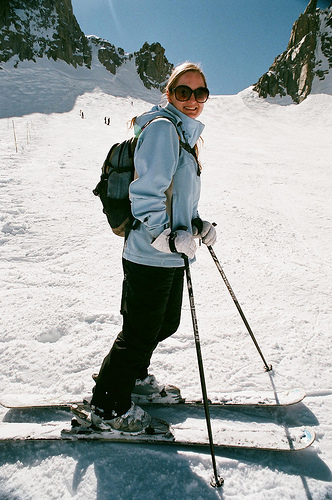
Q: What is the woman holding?
A: Ski poles.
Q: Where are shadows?
A: On the snow.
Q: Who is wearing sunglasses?
A: The woman.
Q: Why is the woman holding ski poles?
A: To ski.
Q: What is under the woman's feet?
A: Skis.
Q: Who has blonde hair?
A: The skier.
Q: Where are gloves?
A: On woman's hands.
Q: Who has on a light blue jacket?
A: A skiier.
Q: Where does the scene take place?
A: On a ski slope.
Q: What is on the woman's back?
A: A backpack.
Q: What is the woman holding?
A: Ski poles.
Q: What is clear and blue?
A: The sky.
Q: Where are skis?
A: Under woman's feet.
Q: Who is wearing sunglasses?
A: The woman.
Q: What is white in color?
A: The snow.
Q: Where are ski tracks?
A: On the snow.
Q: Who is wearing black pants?
A: A woman.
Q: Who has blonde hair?
A: The skier.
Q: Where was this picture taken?
A: A mountain.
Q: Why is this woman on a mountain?
A: She is skiing.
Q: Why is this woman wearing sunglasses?
A: To shield her eyes.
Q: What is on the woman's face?
A: Sunglasses.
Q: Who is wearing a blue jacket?
A: The woman.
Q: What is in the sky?
A: Nothing.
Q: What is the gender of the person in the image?
A: Female.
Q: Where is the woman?
A: A mountain.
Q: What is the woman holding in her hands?
A: Ski poles.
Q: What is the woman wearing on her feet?
A: Skiis.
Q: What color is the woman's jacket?
A: Blue.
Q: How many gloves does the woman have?
A: Two.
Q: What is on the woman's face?
A: Sunglasses.